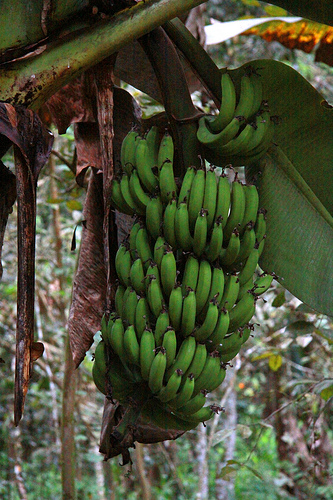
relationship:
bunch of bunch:
[94, 67, 273, 454] [91, 70, 275, 431]